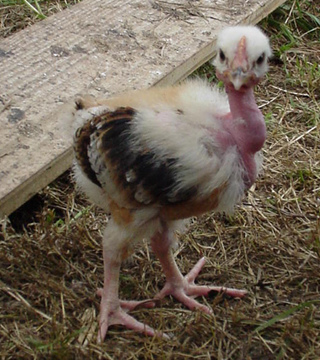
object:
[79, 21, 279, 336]
hen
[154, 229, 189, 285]
legs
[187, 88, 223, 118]
feathers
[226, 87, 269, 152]
neck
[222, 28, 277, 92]
head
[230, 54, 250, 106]
beak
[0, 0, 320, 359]
dry grass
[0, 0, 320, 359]
ground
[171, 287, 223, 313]
toes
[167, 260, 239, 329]
foot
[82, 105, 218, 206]
wing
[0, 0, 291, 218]
board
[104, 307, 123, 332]
webbing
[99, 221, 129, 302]
leg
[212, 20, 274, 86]
face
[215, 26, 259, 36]
fluff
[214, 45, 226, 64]
eye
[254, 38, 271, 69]
eye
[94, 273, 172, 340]
feet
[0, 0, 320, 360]
grass